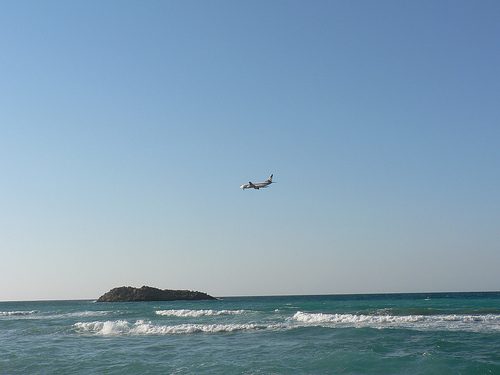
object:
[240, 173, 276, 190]
plane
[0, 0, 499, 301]
sky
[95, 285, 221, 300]
island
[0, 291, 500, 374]
ocean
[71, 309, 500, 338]
wave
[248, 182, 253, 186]
wing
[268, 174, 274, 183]
tail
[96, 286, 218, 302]
trees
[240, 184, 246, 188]
nose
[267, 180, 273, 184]
wing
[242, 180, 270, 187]
body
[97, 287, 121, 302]
edge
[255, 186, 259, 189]
wheel